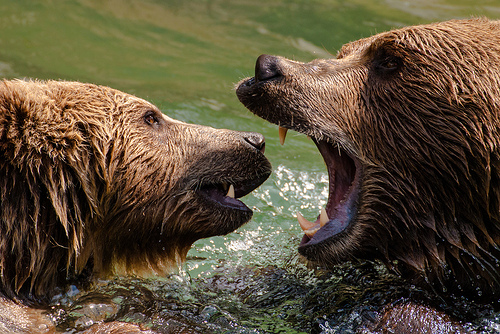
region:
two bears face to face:
[47, 17, 457, 294]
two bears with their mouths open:
[59, 29, 470, 301]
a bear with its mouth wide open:
[273, 21, 447, 319]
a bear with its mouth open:
[40, 96, 261, 258]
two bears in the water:
[54, 30, 476, 244]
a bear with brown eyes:
[46, 94, 266, 249]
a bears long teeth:
[273, 44, 347, 270]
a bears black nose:
[238, 40, 298, 112]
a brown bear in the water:
[1, 56, 256, 293]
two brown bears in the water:
[37, 28, 478, 303]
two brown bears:
[29, 20, 481, 281]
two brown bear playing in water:
[25, 10, 450, 307]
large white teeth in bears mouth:
[271, 116, 301, 163]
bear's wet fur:
[385, 104, 450, 221]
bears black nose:
[242, 43, 296, 100]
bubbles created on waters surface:
[108, 279, 249, 319]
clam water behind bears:
[120, 22, 253, 59]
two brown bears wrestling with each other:
[50, 21, 465, 283]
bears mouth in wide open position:
[237, 40, 344, 284]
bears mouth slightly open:
[193, 113, 270, 231]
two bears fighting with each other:
[26, 33, 427, 266]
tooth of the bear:
[263, 105, 303, 161]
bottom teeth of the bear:
[281, 201, 340, 245]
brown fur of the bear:
[1, 93, 86, 200]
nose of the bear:
[248, 48, 294, 94]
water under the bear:
[233, 230, 288, 312]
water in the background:
[138, 15, 200, 61]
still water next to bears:
[97, 18, 160, 66]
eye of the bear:
[360, 45, 417, 95]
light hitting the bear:
[50, 67, 136, 138]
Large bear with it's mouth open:
[231, 14, 499, 314]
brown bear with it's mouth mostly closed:
[2, 70, 279, 299]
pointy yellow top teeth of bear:
[276, 122, 294, 148]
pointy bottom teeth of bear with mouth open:
[294, 194, 342, 241]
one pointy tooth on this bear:
[219, 180, 241, 206]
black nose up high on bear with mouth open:
[251, 46, 286, 83]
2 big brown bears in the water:
[3, 18, 499, 300]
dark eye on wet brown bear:
[364, 48, 414, 88]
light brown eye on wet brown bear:
[138, 98, 165, 132]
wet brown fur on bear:
[380, 135, 499, 292]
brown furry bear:
[2, 73, 270, 332]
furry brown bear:
[1, 69, 271, 324]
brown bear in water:
[4, 62, 277, 332]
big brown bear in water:
[240, 17, 498, 332]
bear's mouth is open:
[232, 9, 498, 297]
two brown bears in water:
[4, 15, 498, 329]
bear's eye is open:
[117, 92, 183, 137]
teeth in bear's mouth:
[287, 204, 329, 231]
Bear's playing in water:
[0, 16, 497, 332]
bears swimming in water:
[4, 17, 498, 332]